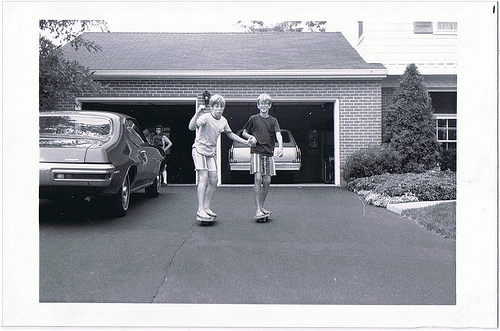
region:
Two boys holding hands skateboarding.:
[187, 86, 282, 219]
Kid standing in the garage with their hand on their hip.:
[148, 121, 172, 188]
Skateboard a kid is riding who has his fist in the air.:
[192, 209, 216, 226]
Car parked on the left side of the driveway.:
[40, 107, 166, 212]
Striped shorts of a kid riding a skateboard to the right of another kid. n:
[245, 147, 275, 177]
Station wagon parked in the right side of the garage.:
[227, 122, 302, 177]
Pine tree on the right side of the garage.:
[385, 62, 442, 172]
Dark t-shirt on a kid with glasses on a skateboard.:
[242, 110, 283, 157]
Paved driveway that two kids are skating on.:
[40, 178, 459, 304]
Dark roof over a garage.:
[41, 31, 386, 78]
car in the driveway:
[45, 110, 166, 232]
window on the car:
[34, 109, 127, 156]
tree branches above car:
[40, 22, 145, 212]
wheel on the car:
[105, 162, 169, 224]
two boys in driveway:
[191, 85, 296, 235]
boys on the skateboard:
[195, 91, 279, 246]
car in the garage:
[227, 111, 334, 190]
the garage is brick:
[108, 74, 369, 109]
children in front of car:
[140, 125, 171, 184]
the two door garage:
[78, 76, 363, 188]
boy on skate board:
[191, 93, 227, 236]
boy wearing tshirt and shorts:
[180, 62, 235, 248]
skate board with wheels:
[180, 187, 227, 238]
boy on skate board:
[230, 80, 300, 232]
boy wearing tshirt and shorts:
[241, 85, 292, 235]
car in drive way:
[36, 92, 181, 202]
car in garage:
[285, 127, 306, 172]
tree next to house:
[385, 60, 435, 175]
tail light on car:
[220, 145, 245, 161]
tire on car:
[103, 162, 148, 219]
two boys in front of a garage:
[188, 85, 282, 232]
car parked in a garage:
[227, 125, 302, 173]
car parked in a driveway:
[26, 110, 168, 212]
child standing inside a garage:
[153, 122, 170, 187]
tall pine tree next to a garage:
[384, 62, 436, 168]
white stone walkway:
[381, 196, 458, 213]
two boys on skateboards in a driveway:
[186, 87, 283, 232]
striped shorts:
[247, 149, 277, 177]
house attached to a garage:
[354, 20, 457, 169]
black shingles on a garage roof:
[46, 30, 386, 69]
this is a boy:
[188, 90, 220, 239]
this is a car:
[54, 109, 144, 212]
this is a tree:
[396, 72, 421, 146]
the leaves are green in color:
[401, 83, 411, 175]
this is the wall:
[340, 83, 363, 146]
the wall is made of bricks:
[347, 86, 369, 128]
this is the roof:
[213, 43, 313, 63]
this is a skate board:
[252, 212, 269, 222]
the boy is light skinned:
[236, 134, 248, 147]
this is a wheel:
[109, 193, 128, 212]